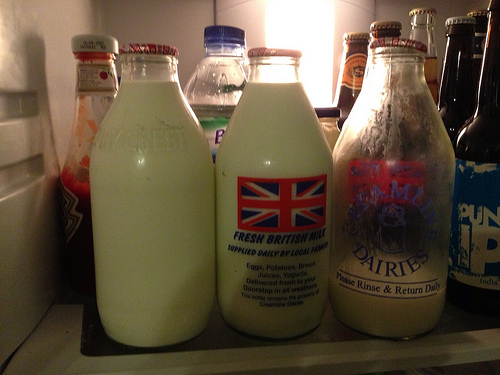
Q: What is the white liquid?
A: Milk.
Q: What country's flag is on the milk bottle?
A: United Kingdom.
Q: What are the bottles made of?
A: Glass.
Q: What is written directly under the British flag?
A: Fresh British Milk.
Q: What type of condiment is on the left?
A: Ketchup.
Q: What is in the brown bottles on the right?
A: Beer.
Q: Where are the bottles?
A: Refrigerator.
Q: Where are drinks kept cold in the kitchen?
A: Refrigerator.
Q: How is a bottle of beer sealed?
A: Cap.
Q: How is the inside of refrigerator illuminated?
A: Light bulb.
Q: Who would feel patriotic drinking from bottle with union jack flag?
A: British.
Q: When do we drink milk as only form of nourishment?
A: Baby.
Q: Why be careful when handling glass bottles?
A: Will break.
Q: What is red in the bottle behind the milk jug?
A: Ketchup.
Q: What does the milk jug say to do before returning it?
A: Rinse the jug.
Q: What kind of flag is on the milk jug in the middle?
A: Union Jack.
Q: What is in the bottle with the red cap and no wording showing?
A: Milk.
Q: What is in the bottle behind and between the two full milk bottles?
A: Water.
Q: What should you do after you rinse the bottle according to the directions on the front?
A: Return it.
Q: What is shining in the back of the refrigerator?
A: Light.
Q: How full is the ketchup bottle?
A: A little over half.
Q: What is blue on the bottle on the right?
A: Logo.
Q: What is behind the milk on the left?
A: Ketchup.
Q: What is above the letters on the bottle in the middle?
A: Flag.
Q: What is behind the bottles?
A: Light.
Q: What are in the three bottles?
A: Milk.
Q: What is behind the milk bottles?
A: A bottle of water.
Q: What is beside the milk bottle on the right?
A: A lot of beer.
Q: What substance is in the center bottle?
A: Milk.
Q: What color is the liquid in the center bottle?
A: White.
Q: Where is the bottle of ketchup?
A: On the left.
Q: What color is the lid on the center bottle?
A: Red.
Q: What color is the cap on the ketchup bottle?
A: White.